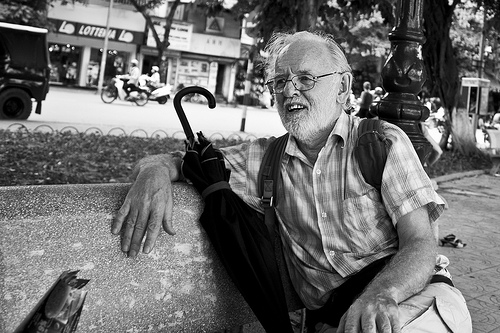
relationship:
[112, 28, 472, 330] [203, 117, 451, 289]
man wearing shirt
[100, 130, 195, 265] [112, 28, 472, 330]
hand of man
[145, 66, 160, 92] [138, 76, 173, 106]
people riding motorcycle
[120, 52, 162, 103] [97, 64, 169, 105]
people on bikes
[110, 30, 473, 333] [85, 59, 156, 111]
man riding a motorcycle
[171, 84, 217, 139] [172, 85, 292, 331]
handle of umbrella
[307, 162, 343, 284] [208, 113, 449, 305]
buttons on shirt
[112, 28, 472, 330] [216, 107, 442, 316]
man wearing shirt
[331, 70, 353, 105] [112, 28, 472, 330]
ear of man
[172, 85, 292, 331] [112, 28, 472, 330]
umbrella next man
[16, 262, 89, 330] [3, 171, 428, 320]
bag on bench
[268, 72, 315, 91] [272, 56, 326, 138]
glasses on face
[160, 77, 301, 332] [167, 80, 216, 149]
umbrella has handle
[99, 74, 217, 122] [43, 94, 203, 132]
motorcyclist on road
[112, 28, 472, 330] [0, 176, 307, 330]
man sitting on bench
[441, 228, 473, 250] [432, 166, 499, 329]
birds standing on sidewalk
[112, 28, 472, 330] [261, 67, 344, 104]
man wearing eyeglasses